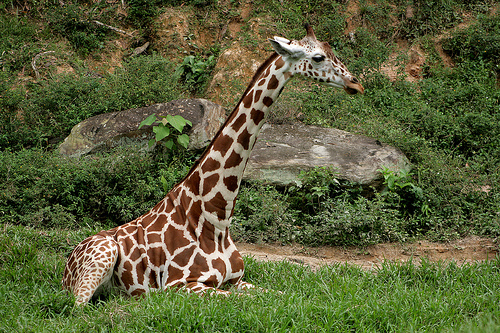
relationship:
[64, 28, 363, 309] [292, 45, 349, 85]
animal has brown spots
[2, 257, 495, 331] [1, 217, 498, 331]
grass in field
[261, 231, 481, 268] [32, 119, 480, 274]
dirt in field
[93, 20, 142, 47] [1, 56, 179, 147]
stick near bushes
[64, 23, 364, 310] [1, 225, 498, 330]
animal on grass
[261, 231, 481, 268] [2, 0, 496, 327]
dirt on ground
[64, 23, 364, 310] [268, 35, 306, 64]
animal has ears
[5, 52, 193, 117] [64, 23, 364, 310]
trees behind animal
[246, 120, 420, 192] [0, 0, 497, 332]
barren rock next to grass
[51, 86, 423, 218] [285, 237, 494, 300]
rocks next to grass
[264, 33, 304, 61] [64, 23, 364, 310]
ear on animal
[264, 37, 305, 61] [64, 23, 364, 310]
ear on animal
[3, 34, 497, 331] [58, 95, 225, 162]
grass covers rock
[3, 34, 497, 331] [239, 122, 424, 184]
grass covers rock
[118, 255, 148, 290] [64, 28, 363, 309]
spots are on a animal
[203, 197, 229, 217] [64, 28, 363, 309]
brown spot are on a animal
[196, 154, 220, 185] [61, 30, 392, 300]
spot on a animal